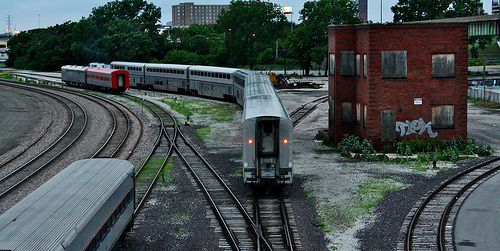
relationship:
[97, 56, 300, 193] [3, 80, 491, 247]
train near tracks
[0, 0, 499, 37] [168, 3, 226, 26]
sky above tall building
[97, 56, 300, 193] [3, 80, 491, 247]
train on tracks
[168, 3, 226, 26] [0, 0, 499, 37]
tall building near sky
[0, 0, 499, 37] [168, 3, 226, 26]
sky near tall building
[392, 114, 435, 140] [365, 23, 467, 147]
graffiti on wall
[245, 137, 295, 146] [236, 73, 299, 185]
dual lights on a train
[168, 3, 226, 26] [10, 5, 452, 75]
tall building behind trees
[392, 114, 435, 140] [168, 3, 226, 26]
graffiti painted on tall building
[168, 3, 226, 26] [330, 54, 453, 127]
tall building with boarded windows